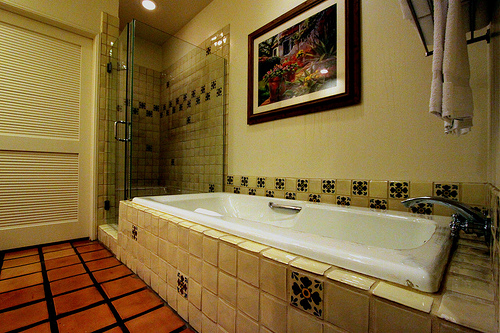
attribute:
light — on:
[139, 0, 161, 17]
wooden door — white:
[0, 27, 103, 227]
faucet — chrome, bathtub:
[396, 192, 491, 242]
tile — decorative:
[287, 275, 321, 320]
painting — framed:
[241, 15, 353, 111]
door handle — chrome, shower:
[109, 117, 130, 145]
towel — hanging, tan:
[427, 2, 474, 134]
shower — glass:
[93, 11, 232, 261]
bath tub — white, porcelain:
[132, 188, 460, 303]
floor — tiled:
[19, 234, 136, 328]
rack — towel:
[411, 0, 498, 55]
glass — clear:
[106, 16, 227, 232]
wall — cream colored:
[168, 2, 495, 214]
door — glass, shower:
[105, 20, 234, 232]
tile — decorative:
[174, 272, 190, 299]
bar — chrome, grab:
[264, 199, 303, 214]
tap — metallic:
[404, 192, 497, 237]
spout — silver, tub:
[399, 188, 491, 249]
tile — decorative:
[277, 266, 332, 322]